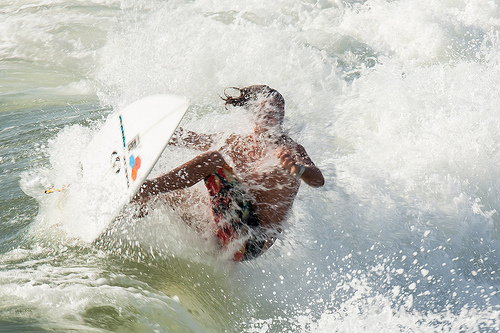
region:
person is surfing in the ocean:
[36, 77, 347, 282]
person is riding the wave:
[54, 67, 321, 283]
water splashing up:
[319, 279, 395, 329]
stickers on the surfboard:
[103, 116, 148, 192]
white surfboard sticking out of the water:
[56, 73, 181, 263]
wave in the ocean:
[39, 262, 233, 331]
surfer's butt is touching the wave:
[186, 90, 313, 277]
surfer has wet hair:
[214, 75, 290, 107]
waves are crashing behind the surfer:
[176, 15, 387, 83]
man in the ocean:
[176, 70, 313, 259]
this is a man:
[183, 74, 325, 281]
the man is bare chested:
[231, 117, 288, 198]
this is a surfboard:
[78, 131, 159, 207]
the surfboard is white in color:
[128, 113, 183, 149]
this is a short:
[221, 179, 274, 239]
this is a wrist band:
[293, 160, 303, 182]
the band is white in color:
[292, 161, 306, 182]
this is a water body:
[341, 96, 428, 290]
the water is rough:
[326, 90, 428, 207]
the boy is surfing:
[88, 60, 316, 307]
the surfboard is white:
[29, 73, 199, 260]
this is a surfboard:
[29, 96, 196, 253]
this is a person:
[140, 84, 320, 276]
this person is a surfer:
[142, 83, 326, 256]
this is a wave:
[22, 93, 240, 332]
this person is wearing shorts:
[133, 79, 345, 267]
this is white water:
[6, 6, 495, 322]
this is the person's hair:
[217, 79, 276, 104]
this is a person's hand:
[274, 148, 326, 203]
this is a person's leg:
[137, 145, 283, 251]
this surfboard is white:
[73, 84, 186, 241]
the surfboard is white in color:
[106, 187, 119, 204]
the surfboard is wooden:
[140, 100, 179, 122]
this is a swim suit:
[213, 179, 259, 264]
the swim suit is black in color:
[255, 238, 265, 256]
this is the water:
[27, 69, 89, 129]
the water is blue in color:
[14, 59, 54, 112]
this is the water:
[360, 80, 445, 230]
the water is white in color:
[380, 169, 458, 250]